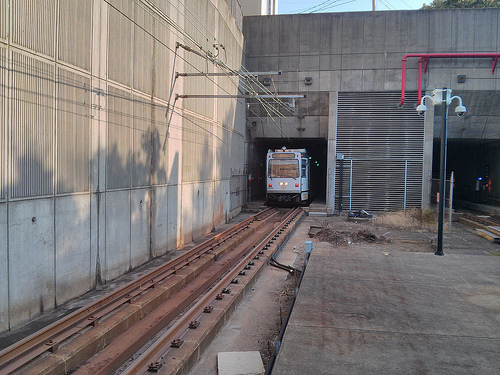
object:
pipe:
[398, 52, 499, 108]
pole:
[437, 87, 447, 252]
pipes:
[393, 51, 498, 105]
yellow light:
[279, 182, 283, 185]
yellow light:
[285, 182, 289, 185]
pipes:
[335, 154, 423, 212]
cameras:
[454, 105, 466, 117]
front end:
[266, 147, 309, 206]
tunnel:
[255, 138, 327, 206]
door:
[334, 91, 425, 213]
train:
[265, 146, 321, 206]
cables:
[101, 0, 305, 146]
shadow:
[194, 143, 214, 237]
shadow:
[219, 87, 255, 216]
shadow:
[0, 126, 180, 336]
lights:
[308, 157, 319, 167]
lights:
[416, 88, 466, 117]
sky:
[267, 0, 434, 17]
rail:
[0, 206, 308, 374]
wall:
[0, 0, 500, 338]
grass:
[371, 202, 437, 231]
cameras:
[416, 105, 428, 116]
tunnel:
[431, 137, 500, 212]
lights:
[477, 177, 483, 180]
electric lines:
[126, 0, 409, 143]